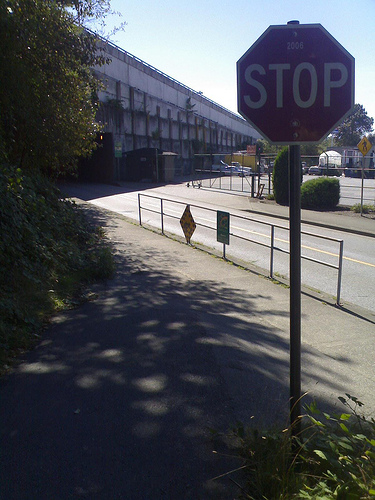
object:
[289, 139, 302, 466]
pole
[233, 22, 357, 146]
sign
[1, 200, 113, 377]
grass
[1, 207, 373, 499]
concrete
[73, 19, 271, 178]
bridge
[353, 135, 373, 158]
sign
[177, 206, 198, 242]
street sign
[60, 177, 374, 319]
road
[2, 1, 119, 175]
trees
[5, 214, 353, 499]
shadow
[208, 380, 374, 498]
plant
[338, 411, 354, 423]
leaves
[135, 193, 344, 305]
fence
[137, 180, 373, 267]
line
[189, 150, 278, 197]
gate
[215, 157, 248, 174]
cars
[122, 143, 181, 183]
dumpster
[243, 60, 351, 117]
stop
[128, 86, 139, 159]
pipes